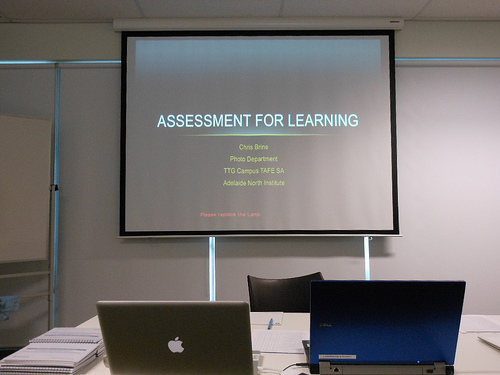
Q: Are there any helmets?
A: No, there are no helmets.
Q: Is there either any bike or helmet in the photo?
A: No, there are no helmets or bikes.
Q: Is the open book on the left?
A: Yes, the book is on the left of the image.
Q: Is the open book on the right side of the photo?
A: No, the book is on the left of the image.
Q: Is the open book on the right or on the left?
A: The book is on the left of the image.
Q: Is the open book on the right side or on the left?
A: The book is on the left of the image.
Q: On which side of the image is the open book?
A: The book is on the left of the image.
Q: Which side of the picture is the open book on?
A: The book is on the left of the image.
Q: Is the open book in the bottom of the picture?
A: Yes, the book is in the bottom of the image.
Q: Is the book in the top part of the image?
A: No, the book is in the bottom of the image.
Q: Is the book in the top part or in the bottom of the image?
A: The book is in the bottom of the image.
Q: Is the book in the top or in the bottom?
A: The book is in the bottom of the image.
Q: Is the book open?
A: Yes, the book is open.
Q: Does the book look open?
A: Yes, the book is open.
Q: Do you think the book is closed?
A: No, the book is open.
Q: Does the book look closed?
A: No, the book is open.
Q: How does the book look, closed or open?
A: The book is open.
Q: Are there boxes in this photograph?
A: No, there are no boxes.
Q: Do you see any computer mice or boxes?
A: No, there are no boxes or computer mice.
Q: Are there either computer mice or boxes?
A: No, there are no boxes or computer mice.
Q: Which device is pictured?
A: The device is a screen.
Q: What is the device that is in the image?
A: The device is a screen.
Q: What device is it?
A: The device is a screen.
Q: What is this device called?
A: That is a screen.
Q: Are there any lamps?
A: No, there are no lamps.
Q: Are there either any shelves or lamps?
A: No, there are no lamps or shelves.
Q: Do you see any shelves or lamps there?
A: No, there are no lamps or shelves.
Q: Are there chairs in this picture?
A: Yes, there is a chair.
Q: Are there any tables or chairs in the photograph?
A: Yes, there is a chair.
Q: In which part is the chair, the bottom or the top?
A: The chair is in the bottom of the image.